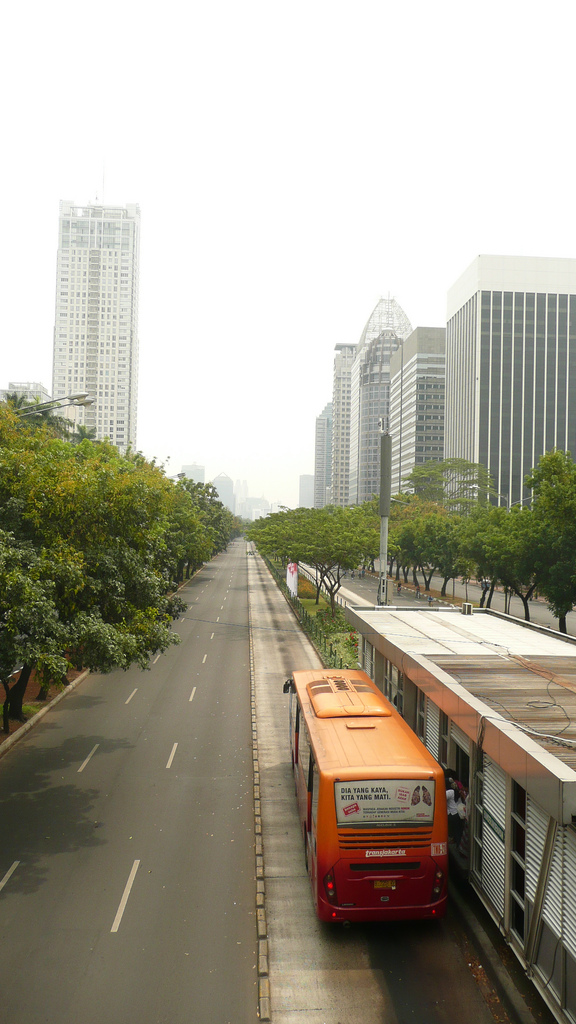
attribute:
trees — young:
[257, 499, 386, 581]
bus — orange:
[260, 667, 450, 941]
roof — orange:
[292, 665, 439, 779]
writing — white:
[361, 842, 413, 858]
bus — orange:
[278, 661, 454, 919]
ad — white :
[331, 779, 435, 830]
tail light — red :
[320, 872, 340, 893]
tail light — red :
[423, 906, 443, 917]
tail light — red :
[323, 910, 345, 921]